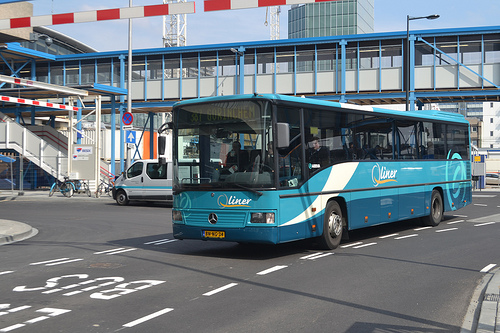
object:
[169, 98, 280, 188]
window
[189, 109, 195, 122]
number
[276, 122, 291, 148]
mirror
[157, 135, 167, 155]
mirror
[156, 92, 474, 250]
bus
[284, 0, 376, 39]
building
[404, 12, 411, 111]
lightpole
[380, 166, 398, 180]
word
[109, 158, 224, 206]
white van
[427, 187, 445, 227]
back tire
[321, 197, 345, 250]
tire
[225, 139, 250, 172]
person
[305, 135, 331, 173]
passengers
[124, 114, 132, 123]
lines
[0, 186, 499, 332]
road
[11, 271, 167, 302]
word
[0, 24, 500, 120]
bridge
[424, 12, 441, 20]
light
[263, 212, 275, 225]
headlight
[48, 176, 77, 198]
bicycle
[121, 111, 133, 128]
circle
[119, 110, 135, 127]
sign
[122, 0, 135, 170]
pole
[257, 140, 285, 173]
driver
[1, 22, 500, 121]
walkway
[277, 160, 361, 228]
stripe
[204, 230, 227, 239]
plate